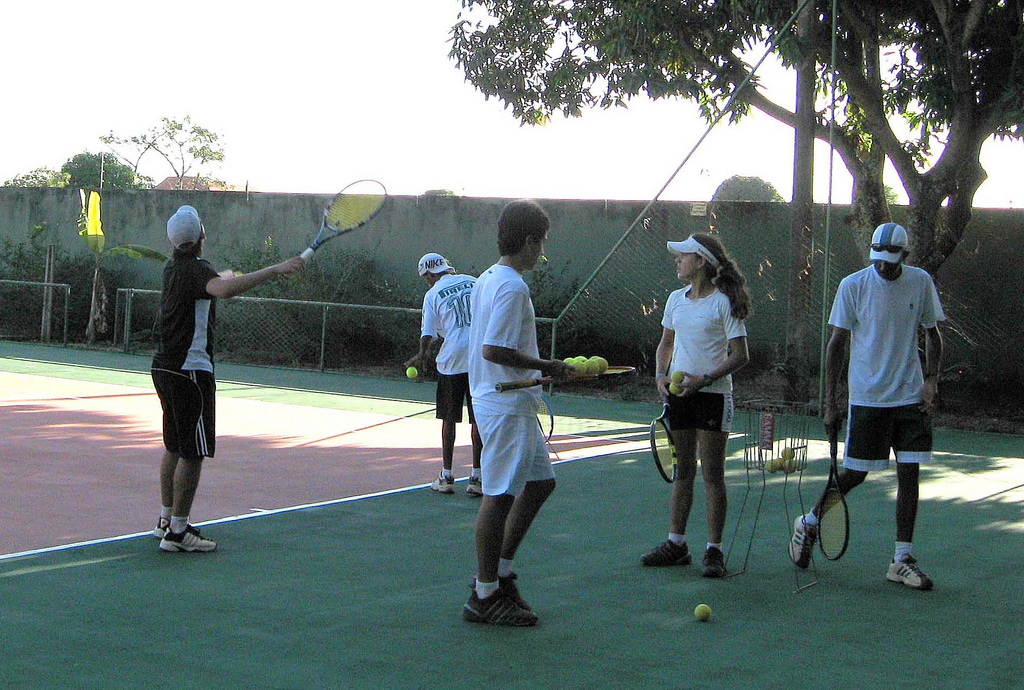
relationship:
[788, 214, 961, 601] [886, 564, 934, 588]
person has foot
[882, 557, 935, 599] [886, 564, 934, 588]
shoe on foot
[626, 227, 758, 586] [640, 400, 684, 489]
girl holding tennis racket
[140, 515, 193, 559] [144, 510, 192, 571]
shoe on foot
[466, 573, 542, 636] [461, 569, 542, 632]
shoe on foot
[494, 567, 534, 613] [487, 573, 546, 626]
shoe on foot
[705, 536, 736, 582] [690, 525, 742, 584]
shoe on foot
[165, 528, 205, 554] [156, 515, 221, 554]
shoe on foot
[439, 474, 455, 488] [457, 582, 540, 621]
shoe on foot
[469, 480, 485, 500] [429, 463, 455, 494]
shoe on foot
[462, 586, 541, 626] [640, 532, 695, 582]
shoe on foot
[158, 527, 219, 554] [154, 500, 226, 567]
shoe on foot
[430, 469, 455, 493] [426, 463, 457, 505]
shoe on foot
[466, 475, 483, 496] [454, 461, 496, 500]
shoe on foot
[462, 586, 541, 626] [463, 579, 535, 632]
shoe on foot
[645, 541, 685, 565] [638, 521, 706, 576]
shoe on foot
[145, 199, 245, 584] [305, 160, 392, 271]
boy holding racket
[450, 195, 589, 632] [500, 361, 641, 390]
boy holding racket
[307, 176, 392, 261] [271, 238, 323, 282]
racket with handle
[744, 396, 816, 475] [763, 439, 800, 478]
basket filled with balls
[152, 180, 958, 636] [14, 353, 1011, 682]
people standing near court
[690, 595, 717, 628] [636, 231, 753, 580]
ball sitting in front of girl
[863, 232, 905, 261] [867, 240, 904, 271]
sunglasses resting on brim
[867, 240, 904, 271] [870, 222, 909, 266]
brim of cap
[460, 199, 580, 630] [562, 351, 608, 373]
boy holding balls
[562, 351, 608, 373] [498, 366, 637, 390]
balls on racket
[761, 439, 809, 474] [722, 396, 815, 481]
balls sitting in basket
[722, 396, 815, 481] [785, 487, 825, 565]
basket with leg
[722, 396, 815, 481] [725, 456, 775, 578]
basket with leg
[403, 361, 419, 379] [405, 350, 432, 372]
ball beneath hand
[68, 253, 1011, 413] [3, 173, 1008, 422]
greenery between wall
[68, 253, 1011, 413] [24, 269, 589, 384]
greenery between fence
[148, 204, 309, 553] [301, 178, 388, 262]
boy holding racket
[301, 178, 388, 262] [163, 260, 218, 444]
racket away from body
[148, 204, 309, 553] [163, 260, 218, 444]
boy has body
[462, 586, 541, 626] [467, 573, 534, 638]
shoe on foot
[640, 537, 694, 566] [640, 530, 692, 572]
shoe on foot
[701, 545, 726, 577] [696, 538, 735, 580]
shoe on foot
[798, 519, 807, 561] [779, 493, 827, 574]
shoe on foot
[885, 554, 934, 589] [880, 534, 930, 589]
shoe on foot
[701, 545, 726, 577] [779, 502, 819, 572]
shoe on foot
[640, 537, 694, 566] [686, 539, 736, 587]
shoe on foot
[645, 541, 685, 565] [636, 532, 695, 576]
shoe on foot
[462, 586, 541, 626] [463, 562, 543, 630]
shoe on foot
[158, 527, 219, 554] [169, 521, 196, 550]
shoe on foot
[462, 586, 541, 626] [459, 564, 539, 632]
shoe on foot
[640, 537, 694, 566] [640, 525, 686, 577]
shoe on foot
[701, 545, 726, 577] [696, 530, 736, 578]
shoe on foot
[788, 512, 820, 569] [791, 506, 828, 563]
shoe on foot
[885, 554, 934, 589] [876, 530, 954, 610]
shoe on foot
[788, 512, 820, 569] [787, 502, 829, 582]
shoe on foot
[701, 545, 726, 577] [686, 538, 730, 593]
shoe on foot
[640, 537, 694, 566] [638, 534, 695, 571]
shoe on foot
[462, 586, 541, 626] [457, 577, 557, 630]
shoe on foot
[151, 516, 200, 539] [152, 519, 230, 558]
shoe on foot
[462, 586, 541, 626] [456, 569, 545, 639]
shoe on foot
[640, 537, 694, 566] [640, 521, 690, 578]
shoe on foot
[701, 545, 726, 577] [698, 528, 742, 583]
shoe on foot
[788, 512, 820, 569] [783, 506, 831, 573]
shoe on foot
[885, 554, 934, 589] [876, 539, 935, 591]
shoe on foot